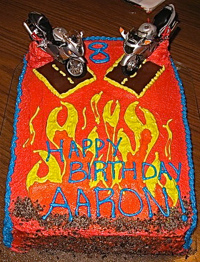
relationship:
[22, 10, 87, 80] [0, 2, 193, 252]
bike sitting on top of cake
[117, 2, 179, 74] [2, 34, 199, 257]
motorcycle on a cake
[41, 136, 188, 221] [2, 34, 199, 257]
text written on cake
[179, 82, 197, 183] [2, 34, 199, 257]
icing outlining a cake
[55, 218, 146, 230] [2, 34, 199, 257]
sprinkles on bottom of a cake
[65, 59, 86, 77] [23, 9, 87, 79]
front wheel of a toy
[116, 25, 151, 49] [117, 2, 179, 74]
mirrors on a toy motorcycle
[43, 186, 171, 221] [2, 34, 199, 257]
aaron on cake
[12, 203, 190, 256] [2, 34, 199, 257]
stuff on cake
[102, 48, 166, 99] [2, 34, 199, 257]
road on cake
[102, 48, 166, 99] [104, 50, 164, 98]
road on cake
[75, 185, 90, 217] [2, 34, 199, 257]
blue a on cake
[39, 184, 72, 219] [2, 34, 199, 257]
blue a on cake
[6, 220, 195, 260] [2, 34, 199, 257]
cake side of cake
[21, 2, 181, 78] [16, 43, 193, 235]
bike on cake